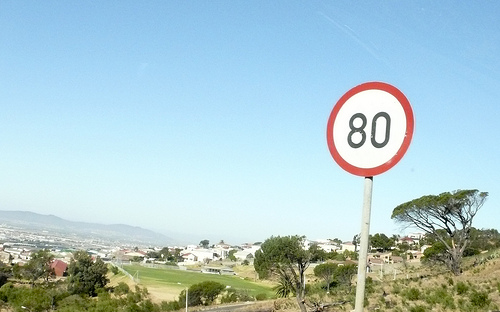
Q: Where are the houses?
A: Off in the distance.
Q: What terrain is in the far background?
A: Mountains.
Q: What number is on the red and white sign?
A: 80.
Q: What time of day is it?
A: Afternoon.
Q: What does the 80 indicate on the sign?
A: Speed limit.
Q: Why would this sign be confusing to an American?
A: It's much different than speed limit signs there.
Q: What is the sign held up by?
A: A metal pole.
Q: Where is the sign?
A: On the metal pole.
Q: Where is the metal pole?
A: Under the sign.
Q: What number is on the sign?
A: 80.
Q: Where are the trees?
A: On the hill.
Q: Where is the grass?
A: On the ground.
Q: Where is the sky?
A: Above the sign.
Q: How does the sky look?
A: Clear.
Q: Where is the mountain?
A: Beyond the field.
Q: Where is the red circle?
A: On the sign.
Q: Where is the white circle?
A: On the sign.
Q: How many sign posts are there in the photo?
A: 1.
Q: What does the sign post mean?
A: Speed at 80.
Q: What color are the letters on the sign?
A: Black.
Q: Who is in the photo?
A: No one.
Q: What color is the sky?
A: Blue.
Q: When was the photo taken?
A: Day time.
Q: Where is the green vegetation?
A: Behind the sign post.